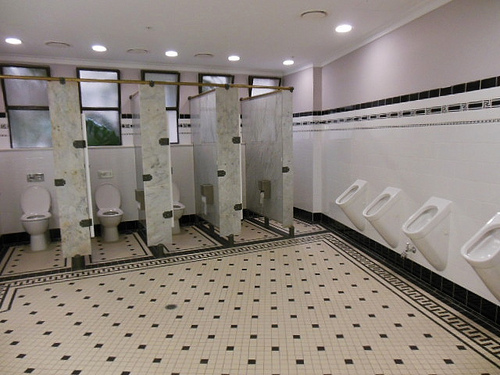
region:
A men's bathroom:
[25, 55, 491, 345]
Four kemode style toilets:
[15, 170, 272, 247]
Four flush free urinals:
[334, 170, 496, 292]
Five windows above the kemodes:
[1, 65, 301, 153]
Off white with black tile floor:
[28, 290, 463, 370]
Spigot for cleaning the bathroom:
[402, 240, 419, 260]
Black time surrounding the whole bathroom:
[463, 291, 498, 323]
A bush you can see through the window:
[88, 110, 126, 147]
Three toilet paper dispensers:
[136, 184, 292, 210]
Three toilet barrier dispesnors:
[24, 163, 186, 182]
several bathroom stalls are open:
[2, 95, 326, 264]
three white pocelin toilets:
[8, 160, 198, 255]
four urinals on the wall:
[322, 157, 497, 280]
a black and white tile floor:
[15, 255, 479, 373]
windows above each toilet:
[4, 62, 303, 158]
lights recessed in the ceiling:
[6, 29, 371, 77]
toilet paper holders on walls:
[129, 176, 283, 228]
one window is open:
[83, 69, 135, 153]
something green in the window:
[87, 112, 124, 150]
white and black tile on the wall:
[300, 91, 498, 283]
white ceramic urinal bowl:
[336, 178, 366, 232]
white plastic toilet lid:
[21, 185, 50, 215]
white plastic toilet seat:
[21, 210, 51, 222]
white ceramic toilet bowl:
[21, 217, 49, 254]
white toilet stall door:
[79, 110, 98, 237]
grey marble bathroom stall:
[130, 82, 174, 251]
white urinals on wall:
[333, 177, 498, 310]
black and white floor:
[1, 234, 498, 371]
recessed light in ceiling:
[336, 21, 352, 34]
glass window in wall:
[79, 71, 124, 146]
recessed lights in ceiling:
[8, 22, 353, 67]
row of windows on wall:
[2, 65, 285, 148]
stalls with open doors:
[1, 73, 296, 266]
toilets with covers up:
[18, 182, 183, 252]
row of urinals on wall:
[332, 179, 498, 299]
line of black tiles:
[296, 76, 498, 118]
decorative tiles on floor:
[321, 232, 498, 374]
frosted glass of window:
[8, 108, 53, 150]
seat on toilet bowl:
[96, 208, 124, 218]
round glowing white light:
[227, 53, 239, 63]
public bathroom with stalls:
[30, 55, 320, 268]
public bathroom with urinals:
[321, 167, 497, 307]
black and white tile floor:
[156, 252, 344, 371]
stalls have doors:
[152, 99, 254, 238]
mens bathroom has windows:
[30, 55, 317, 154]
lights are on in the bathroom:
[48, 15, 316, 90]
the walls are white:
[345, 50, 472, 185]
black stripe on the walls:
[313, 87, 498, 133]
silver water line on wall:
[394, 240, 417, 260]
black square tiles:
[184, 317, 226, 351]